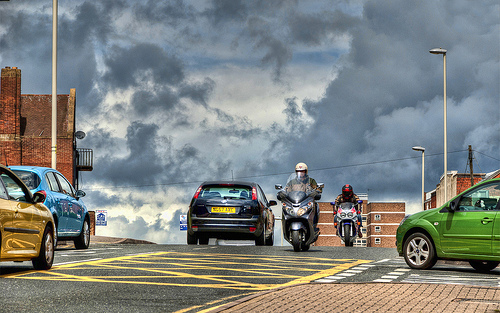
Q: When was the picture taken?
A: Daytime.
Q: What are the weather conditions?
A: Very cloudy.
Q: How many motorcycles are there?
A: Two.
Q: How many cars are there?
A: Four.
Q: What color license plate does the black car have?
A: Yellow.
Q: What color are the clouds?
A: Dark gray.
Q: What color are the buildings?
A: Brown.